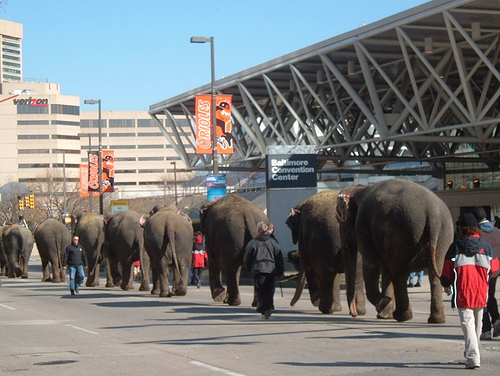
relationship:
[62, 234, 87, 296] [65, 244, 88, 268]
man wears jacket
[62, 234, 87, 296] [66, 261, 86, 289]
man wears jeans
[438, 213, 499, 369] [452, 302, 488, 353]
man wears beige pants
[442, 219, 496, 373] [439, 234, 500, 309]
man wearing jacket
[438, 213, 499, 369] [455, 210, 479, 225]
man wearing black hat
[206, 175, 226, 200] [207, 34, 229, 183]
blue sign on pole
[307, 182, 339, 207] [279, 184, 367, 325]
dirt on elephant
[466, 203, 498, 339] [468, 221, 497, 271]
man wearing jacket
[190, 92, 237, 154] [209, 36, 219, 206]
sign attached to pole